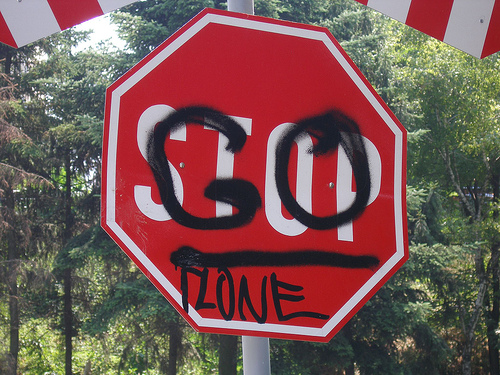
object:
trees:
[0, 56, 55, 366]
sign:
[90, 4, 411, 353]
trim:
[310, 25, 406, 134]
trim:
[201, 11, 330, 47]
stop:
[134, 103, 381, 242]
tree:
[32, 40, 97, 373]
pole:
[239, 335, 269, 373]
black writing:
[147, 103, 377, 314]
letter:
[140, 101, 262, 237]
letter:
[261, 119, 318, 238]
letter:
[171, 264, 218, 315]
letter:
[213, 262, 237, 322]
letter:
[236, 272, 271, 325]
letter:
[266, 270, 333, 326]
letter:
[131, 99, 196, 221]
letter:
[197, 110, 259, 229]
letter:
[327, 127, 385, 245]